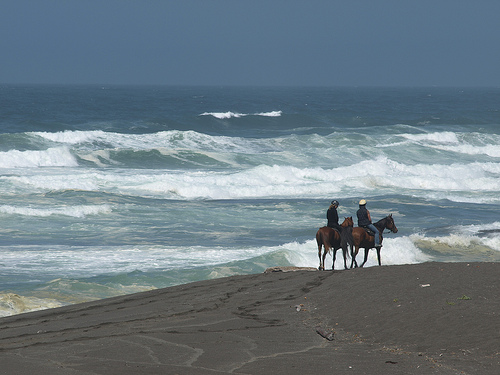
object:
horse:
[341, 213, 398, 269]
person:
[356, 198, 382, 247]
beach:
[0, 260, 498, 374]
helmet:
[358, 199, 367, 204]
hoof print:
[284, 294, 297, 302]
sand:
[0, 260, 499, 374]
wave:
[199, 110, 283, 118]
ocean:
[0, 84, 499, 318]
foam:
[416, 239, 499, 259]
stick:
[420, 283, 431, 288]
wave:
[176, 233, 434, 271]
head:
[383, 213, 398, 233]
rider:
[327, 199, 348, 247]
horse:
[316, 216, 354, 270]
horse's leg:
[321, 242, 329, 270]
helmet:
[330, 199, 337, 207]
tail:
[340, 227, 350, 261]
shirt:
[356, 208, 373, 227]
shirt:
[327, 208, 339, 225]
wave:
[0, 130, 499, 217]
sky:
[1, 0, 500, 85]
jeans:
[363, 223, 381, 246]